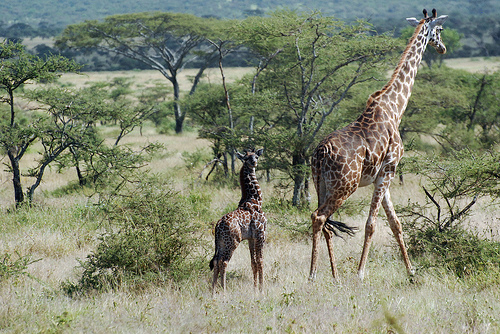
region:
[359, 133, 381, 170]
part of a stomach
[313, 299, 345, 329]
part of some grass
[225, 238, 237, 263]
part of a thigh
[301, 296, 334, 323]
part of a ground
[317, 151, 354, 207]
part of t a thigh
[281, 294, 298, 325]
part of a grass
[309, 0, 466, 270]
this is a giraffe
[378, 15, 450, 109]
the giraffe has long neck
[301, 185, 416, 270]
the legs are long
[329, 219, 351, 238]
the tail is wavy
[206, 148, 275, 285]
this is the small giraffe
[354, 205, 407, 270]
the legs re apart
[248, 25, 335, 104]
the trees are tall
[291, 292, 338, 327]
the grass are brown in color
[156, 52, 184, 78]
the branches re dry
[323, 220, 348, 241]
the tail is black in color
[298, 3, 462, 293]
mom giraffe - tall, dignified - ignoring photographer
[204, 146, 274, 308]
baby giraffe whips head on neck nearly backwards to inspect present intrusion [the photographer]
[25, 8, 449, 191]
flat topped trees are called 'flat top acacia' & are common to much of africa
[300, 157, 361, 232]
mom giraffe has knobby angular hip, knobby angular knee pointed backward [if one is a human]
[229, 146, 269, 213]
baby giraffe is frankly curious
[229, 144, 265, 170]
baby giraffe has dark face, dark ears, dark topknots atop darkish horns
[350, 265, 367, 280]
mom giraffe has @ least one spotless cream colour built-in sock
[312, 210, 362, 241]
mom giraffe's tail tip blows eastward [to the right]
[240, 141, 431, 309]
baby giraffe+mom giraffe have long slender forelegs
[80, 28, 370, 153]
flat top acacia trunks+branches are dark grey -> black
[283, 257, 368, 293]
the grass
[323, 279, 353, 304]
the grass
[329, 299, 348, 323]
the grass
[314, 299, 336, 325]
the grass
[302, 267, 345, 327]
the grass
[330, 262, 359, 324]
the grass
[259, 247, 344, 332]
the grass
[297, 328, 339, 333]
the grass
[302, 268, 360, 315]
the grass is dry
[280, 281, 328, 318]
the grass is dry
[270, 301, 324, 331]
the grass is dry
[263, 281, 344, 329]
the grass is dry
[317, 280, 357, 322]
the grass is dry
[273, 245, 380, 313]
the grass is dry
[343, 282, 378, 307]
the grass is dry